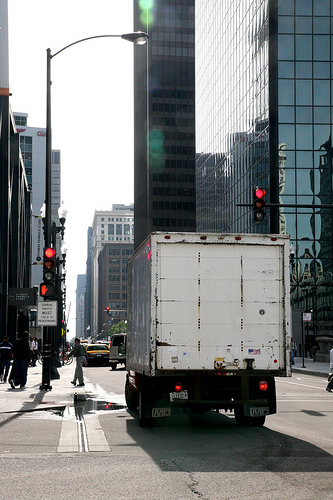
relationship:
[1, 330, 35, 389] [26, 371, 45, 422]
people at sidewalk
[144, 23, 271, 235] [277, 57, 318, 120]
building made of glass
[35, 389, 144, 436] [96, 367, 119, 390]
puddle on street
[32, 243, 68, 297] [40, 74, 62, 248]
traffic light attached to pole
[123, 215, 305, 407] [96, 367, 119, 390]
truck at street